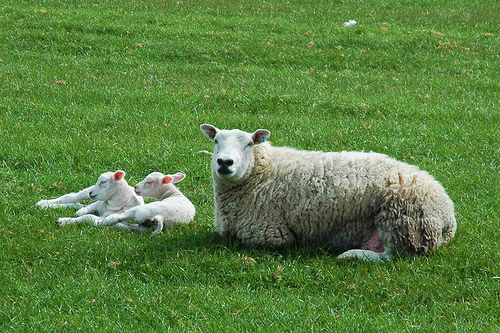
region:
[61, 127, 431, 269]
three sheep on grass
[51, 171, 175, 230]
two lambs are white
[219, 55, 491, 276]
adult sheep is brown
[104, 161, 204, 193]
lambs have pink ears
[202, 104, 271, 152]
adult sheep has white ears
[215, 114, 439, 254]
sheep has thick fur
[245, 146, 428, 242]
sheep's fur is light brown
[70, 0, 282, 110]
grass is green and thick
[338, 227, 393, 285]
sheep has white feet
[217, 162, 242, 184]
sheep has black nose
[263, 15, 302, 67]
part of a ground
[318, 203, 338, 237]
part of a sheep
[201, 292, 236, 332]
part of a grass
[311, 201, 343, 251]
part of a sheep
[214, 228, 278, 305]
part of a sheep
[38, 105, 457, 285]
three sheep laying on the grass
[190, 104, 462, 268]
an adult sheep laying on the grass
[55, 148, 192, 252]
two lambs laying on the grass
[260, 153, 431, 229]
grey fleece of the sheep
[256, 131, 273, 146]
blue tag in the sheeps ear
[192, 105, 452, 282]
a sheep looking at the camera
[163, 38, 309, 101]
green grass of the field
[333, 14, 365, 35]
a small white plant growing in the field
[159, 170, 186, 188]
pink ears of the lamb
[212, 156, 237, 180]
black nose and mouth of the sheep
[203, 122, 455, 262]
this is a sheep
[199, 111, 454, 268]
the sheep is relaxing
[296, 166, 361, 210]
this is the wool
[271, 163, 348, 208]
the wool is grey in color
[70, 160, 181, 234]
these are the kids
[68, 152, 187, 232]
the kids are two in number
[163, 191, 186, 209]
the kid is white in color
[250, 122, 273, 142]
this is the ear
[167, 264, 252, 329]
these are the grass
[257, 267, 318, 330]
the grass is green in color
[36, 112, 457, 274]
two lambs and mother sheep laying on the ground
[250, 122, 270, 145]
the ear of a sheep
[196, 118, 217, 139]
the ear of a sheep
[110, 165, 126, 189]
the ear of a lamb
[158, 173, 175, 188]
the ear of a lamb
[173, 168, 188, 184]
the ear of a lamb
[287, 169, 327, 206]
the wool on a sheep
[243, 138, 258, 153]
the eye of a sheep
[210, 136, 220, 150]
the eye of a sheep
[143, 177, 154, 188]
the eye of a lamb